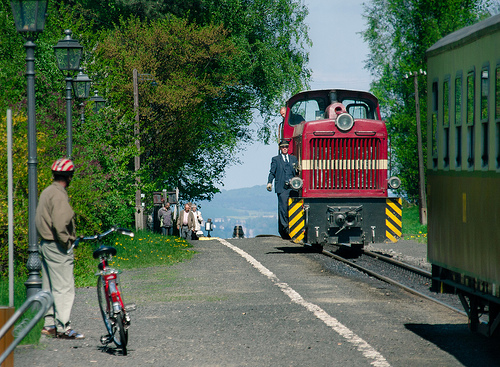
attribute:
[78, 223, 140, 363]
bike — red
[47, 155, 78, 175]
helmet — red , white, striped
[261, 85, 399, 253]
engine — train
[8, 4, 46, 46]
lamp — street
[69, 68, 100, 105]
lamp — street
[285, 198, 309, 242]
warning sign — yellow, black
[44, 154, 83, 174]
helmet — white, red, striped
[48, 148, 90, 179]
safety helmet — red, white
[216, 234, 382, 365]
white safety line — long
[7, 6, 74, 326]
metal light post — tall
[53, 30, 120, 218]
grey light pole — large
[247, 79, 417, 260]
train engine — red, black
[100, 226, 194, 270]
flowers dotting — yellow